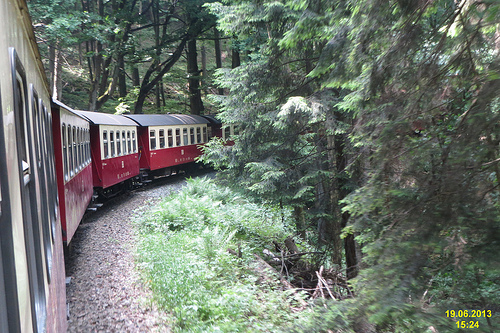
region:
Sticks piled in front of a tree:
[306, 269, 334, 308]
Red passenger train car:
[89, 116, 146, 188]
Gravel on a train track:
[77, 237, 152, 323]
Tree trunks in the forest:
[316, 138, 356, 275]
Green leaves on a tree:
[208, 50, 295, 192]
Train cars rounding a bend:
[40, 74, 217, 215]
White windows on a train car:
[145, 126, 201, 144]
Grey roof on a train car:
[132, 106, 204, 123]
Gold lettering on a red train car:
[172, 153, 195, 163]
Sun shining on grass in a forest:
[140, 211, 217, 328]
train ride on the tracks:
[15, 22, 216, 163]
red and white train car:
[92, 111, 139, 186]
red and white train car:
[140, 107, 222, 172]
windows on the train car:
[151, 115, 203, 145]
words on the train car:
[109, 159, 141, 179]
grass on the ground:
[165, 230, 237, 332]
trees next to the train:
[230, 68, 373, 265]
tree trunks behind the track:
[96, 49, 196, 103]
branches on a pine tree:
[346, 67, 448, 292]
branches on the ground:
[269, 233, 339, 295]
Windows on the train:
[152, 123, 187, 142]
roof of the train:
[139, 114, 171, 127]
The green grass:
[147, 7, 230, 202]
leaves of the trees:
[232, 77, 302, 177]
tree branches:
[281, 260, 372, 315]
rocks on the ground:
[90, 237, 122, 327]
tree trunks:
[101, 38, 154, 89]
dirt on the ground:
[60, 65, 85, 95]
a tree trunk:
[172, 40, 213, 96]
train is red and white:
[99, 133, 142, 179]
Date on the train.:
[432, 300, 499, 332]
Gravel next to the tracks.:
[92, 278, 136, 323]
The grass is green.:
[191, 276, 247, 317]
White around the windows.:
[89, 115, 152, 157]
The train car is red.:
[93, 151, 147, 184]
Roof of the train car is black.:
[85, 108, 152, 130]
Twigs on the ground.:
[280, 259, 351, 296]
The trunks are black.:
[83, 65, 180, 102]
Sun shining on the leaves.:
[271, 89, 322, 123]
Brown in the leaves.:
[353, 107, 441, 157]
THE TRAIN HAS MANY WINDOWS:
[58, 102, 213, 187]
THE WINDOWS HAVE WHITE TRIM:
[61, 109, 210, 186]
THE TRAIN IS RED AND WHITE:
[2, 0, 249, 329]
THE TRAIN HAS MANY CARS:
[0, 0, 253, 332]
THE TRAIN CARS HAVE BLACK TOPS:
[3, 0, 233, 132]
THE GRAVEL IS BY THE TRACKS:
[71, 171, 236, 331]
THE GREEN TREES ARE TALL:
[201, 0, 498, 331]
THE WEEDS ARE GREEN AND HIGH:
[132, 172, 348, 331]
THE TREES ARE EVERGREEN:
[201, 0, 498, 332]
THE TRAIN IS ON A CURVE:
[3, 2, 258, 332]